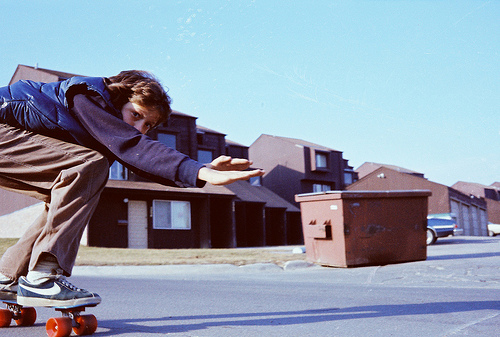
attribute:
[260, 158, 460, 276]
dumster — large, brown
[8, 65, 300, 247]
house — brown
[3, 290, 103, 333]
skateboard — boys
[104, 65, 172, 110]
hair — brown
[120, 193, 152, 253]
door — closed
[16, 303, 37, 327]
wheel — red, plastic, skate board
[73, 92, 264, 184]
arm — stretched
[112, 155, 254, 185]
arm — stretched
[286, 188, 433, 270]
dumpster — large, brown, metal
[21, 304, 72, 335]
wheel — red, plastic, skateboard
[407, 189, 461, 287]
car — blue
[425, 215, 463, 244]
car — parked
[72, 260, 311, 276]
curb — concrete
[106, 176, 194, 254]
door — white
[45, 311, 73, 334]
wheel — red, plastic, skateboard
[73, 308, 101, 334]
wheel — red, plastic, skateboard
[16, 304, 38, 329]
wheel — red, plastic, skateboard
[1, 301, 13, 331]
wheel — red, plastic, skateboard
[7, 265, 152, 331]
board — for skate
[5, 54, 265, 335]
boy — riding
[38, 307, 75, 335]
wheel — red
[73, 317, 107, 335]
wheel — red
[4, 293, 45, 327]
wheel — red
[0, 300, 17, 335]
wheel — red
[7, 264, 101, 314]
shoes — blue, white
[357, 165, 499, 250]
garages — double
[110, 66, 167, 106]
hair — long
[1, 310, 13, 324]
wheel — red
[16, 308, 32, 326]
wheel — red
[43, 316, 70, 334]
wheel — red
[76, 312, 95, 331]
wheel — red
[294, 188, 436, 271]
trash can — behind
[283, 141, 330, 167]
apartments — brown, suburban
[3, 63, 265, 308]
dude — nascent, young, skateboard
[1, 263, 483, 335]
road — asphalt